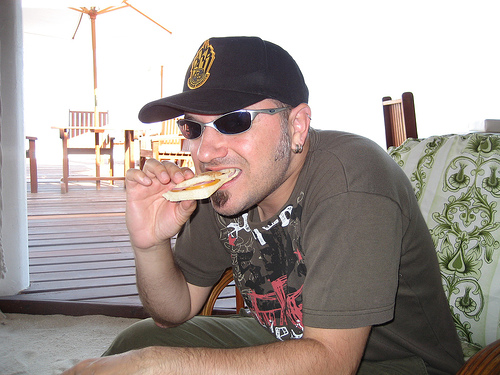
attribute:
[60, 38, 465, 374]
man — eating, sittng, sitting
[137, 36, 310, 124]
cap — a baseball cap, black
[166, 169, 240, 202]
pizza — bitten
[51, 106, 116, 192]
chair — wooden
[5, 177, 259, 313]
deck — wooden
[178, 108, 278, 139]
sunglasses — tinted, silver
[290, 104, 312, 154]
ear — pierced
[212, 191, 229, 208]
soul patch — brown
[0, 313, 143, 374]
shag carpet — beige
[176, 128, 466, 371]
shirt — brown, gray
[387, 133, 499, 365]
blanket — green, white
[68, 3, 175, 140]
table umbrella — large